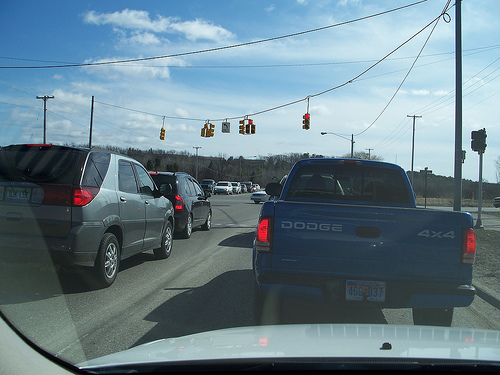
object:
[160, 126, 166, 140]
lights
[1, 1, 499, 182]
blue sky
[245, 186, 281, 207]
left turn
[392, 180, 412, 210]
ground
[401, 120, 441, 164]
ground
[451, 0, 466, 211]
pole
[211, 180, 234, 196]
car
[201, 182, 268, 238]
intersection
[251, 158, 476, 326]
car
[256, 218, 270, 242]
brake lights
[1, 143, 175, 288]
car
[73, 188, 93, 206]
light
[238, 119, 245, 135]
street light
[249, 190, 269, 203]
car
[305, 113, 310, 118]
light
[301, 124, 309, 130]
light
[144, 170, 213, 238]
black van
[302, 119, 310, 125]
light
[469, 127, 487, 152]
sign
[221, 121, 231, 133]
traffic sign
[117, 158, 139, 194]
windows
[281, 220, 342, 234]
lettering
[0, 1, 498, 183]
cloud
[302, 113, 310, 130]
stop light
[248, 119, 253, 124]
lights